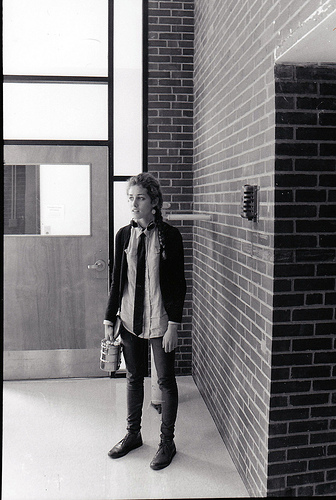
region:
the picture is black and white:
[0, 0, 334, 497]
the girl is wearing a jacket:
[105, 217, 188, 335]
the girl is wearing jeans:
[115, 315, 180, 450]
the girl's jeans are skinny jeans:
[114, 319, 180, 447]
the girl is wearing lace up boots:
[95, 427, 182, 475]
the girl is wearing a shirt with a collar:
[129, 220, 161, 238]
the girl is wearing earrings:
[148, 203, 157, 216]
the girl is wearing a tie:
[133, 229, 146, 337]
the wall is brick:
[147, 0, 335, 499]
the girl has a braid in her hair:
[124, 171, 171, 265]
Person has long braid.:
[139, 174, 189, 274]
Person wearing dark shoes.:
[109, 434, 190, 495]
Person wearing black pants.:
[112, 376, 193, 435]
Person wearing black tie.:
[130, 258, 156, 343]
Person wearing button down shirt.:
[146, 298, 175, 352]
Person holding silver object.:
[88, 317, 127, 385]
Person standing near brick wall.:
[103, 284, 204, 413]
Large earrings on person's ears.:
[148, 201, 164, 229]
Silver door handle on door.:
[87, 252, 113, 280]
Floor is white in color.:
[53, 429, 217, 494]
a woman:
[109, 159, 298, 435]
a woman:
[104, 315, 226, 491]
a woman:
[74, 240, 229, 451]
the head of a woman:
[121, 168, 167, 219]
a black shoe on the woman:
[147, 433, 179, 470]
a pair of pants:
[116, 328, 183, 444]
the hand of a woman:
[159, 320, 180, 355]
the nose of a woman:
[131, 194, 140, 207]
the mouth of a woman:
[128, 205, 140, 214]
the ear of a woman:
[149, 193, 161, 207]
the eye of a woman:
[135, 192, 146, 201]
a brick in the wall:
[263, 348, 314, 369]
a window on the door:
[3, 159, 96, 240]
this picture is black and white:
[66, 159, 215, 486]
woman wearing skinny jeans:
[114, 315, 186, 467]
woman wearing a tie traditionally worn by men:
[127, 219, 156, 339]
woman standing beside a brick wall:
[115, 156, 259, 405]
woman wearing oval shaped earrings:
[147, 202, 159, 218]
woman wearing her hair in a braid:
[123, 171, 171, 261]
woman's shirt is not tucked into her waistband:
[106, 219, 191, 343]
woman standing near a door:
[3, 134, 159, 382]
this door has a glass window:
[2, 138, 116, 382]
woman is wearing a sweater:
[100, 219, 191, 332]